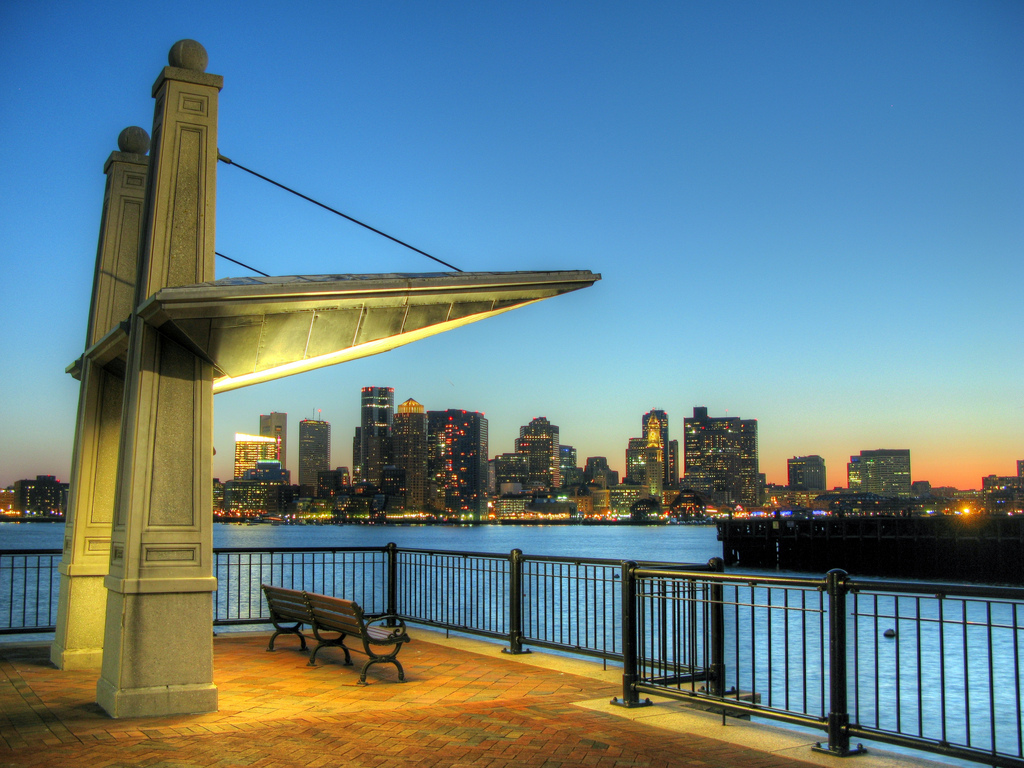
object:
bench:
[260, 582, 412, 686]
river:
[0, 519, 1016, 765]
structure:
[41, 30, 606, 724]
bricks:
[440, 688, 479, 705]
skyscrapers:
[360, 386, 396, 523]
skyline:
[0, 513, 1018, 531]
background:
[0, 0, 1024, 524]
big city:
[0, 384, 1022, 526]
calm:
[0, 519, 1022, 765]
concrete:
[95, 37, 221, 720]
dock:
[0, 612, 972, 768]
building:
[443, 406, 489, 522]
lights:
[448, 432, 454, 437]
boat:
[713, 509, 1022, 587]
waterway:
[0, 521, 1024, 768]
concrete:
[0, 621, 959, 768]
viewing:
[476, 555, 1015, 768]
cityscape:
[0, 382, 1022, 529]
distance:
[0, 0, 1021, 522]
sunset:
[0, 0, 1024, 488]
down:
[0, 618, 961, 768]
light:
[210, 308, 518, 397]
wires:
[215, 250, 273, 278]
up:
[134, 302, 336, 577]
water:
[0, 519, 1021, 765]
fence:
[0, 540, 1024, 768]